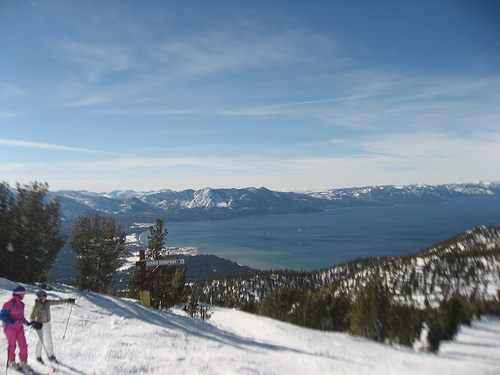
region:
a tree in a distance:
[139, 213, 169, 257]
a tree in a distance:
[76, 214, 127, 298]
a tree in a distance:
[36, 194, 76, 323]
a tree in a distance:
[10, 180, 47, 292]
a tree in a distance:
[172, 264, 189, 303]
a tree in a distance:
[267, 281, 289, 321]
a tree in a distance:
[297, 292, 323, 327]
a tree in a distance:
[346, 286, 376, 348]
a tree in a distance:
[378, 291, 409, 344]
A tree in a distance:
[71, 208, 107, 293]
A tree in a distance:
[143, 217, 170, 264]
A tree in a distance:
[28, 187, 63, 283]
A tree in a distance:
[165, 266, 197, 304]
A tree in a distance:
[257, 286, 288, 327]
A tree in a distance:
[306, 293, 329, 321]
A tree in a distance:
[350, 276, 367, 331]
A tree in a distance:
[432, 294, 454, 339]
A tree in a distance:
[394, 302, 416, 341]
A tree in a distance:
[213, 277, 221, 311]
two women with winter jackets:
[4, 274, 86, 371]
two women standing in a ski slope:
[6, 274, 157, 373]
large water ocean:
[122, 170, 296, 257]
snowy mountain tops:
[164, 172, 260, 218]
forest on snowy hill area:
[249, 229, 464, 354]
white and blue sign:
[138, 243, 200, 296]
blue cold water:
[318, 190, 452, 271]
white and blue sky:
[79, 158, 169, 190]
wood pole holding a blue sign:
[125, 242, 177, 320]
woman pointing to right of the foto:
[32, 284, 107, 367]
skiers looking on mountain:
[1, 279, 78, 373]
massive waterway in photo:
[148, 212, 485, 273]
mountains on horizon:
[61, 176, 496, 228]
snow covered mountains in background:
[52, 177, 498, 209]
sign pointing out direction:
[139, 256, 191, 266]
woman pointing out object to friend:
[1, 280, 83, 371]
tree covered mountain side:
[221, 219, 499, 353]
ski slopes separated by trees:
[201, 240, 499, 368]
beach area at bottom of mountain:
[156, 237, 203, 257]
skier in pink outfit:
[1, 280, 33, 370]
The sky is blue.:
[76, 22, 401, 152]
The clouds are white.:
[106, 125, 469, 187]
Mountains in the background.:
[38, 160, 494, 215]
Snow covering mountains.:
[106, 176, 246, 208]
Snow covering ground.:
[16, 283, 441, 369]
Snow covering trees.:
[223, 250, 449, 328]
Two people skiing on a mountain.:
[0, 270, 82, 367]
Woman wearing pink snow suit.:
[8, 280, 24, 346]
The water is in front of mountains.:
[203, 208, 439, 253]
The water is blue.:
[229, 207, 414, 255]